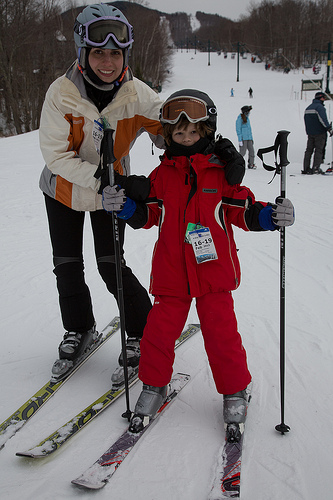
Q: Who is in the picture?
A: A mother and son.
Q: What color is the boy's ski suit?
A: Red.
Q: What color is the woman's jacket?
A: White.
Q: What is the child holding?
A: Poles.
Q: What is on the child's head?
A: Goggles.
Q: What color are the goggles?
A: Red.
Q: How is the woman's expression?
A: She is smiling.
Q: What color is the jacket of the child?
A: Red.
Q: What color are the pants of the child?
A: Red.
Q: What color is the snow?
A: White.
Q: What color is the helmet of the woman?
A: Gray.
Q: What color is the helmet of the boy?
A: Black.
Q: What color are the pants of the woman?
A: Black.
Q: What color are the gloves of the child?
A: Gray and blue.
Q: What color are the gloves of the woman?
A: Black.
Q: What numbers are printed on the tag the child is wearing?
A: 16 and 19.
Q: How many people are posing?
A: Two.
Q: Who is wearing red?
A: Child.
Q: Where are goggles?
A: On skier's heads.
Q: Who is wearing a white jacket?
A: The woman.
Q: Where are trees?
A: In the distance.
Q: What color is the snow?
A: White.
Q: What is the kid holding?
A: Ski poles.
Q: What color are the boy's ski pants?
A: Red.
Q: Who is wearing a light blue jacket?
A: Person in background.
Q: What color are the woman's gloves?
A: Black.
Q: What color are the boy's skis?
A: Red and silver.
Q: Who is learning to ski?
A: The child.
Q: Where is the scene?
A: On a slope.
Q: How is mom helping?
A: Loaning her poles.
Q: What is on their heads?
A: Helmets.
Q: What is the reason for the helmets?
A: Safety.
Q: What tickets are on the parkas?
A: Lift tickets.